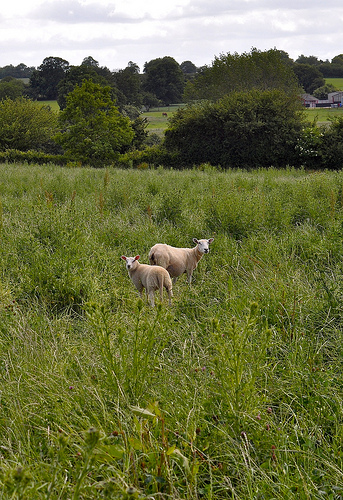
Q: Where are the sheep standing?
A: Field.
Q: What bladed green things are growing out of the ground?
A: Grass.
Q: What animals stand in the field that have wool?
A: Sheep.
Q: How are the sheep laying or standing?
A: Standing.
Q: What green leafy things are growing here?
A: Trees.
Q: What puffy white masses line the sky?
A: Clouds.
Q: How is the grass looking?
A: Healthy.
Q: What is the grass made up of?
A: Blades.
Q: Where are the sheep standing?
A: Field.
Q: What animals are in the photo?
A: Sheep.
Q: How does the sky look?
A: Mostly cloudy.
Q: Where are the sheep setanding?
A: In a grassy field.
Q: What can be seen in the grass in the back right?
A: A house.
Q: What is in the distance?
A: Trees.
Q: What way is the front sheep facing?
A: Left.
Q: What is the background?
A: Grass.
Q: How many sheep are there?
A: Two.